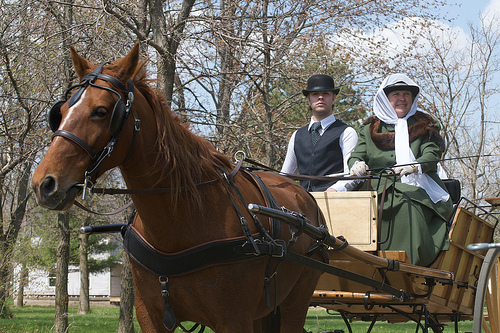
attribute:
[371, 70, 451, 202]
scarf — white 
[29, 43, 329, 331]
horse — brown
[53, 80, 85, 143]
marker — white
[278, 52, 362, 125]
leaves — green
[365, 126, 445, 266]
jacket — green